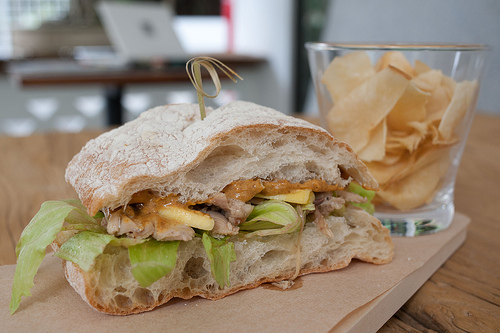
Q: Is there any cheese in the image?
A: Yes, there is cheese.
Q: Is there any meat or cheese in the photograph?
A: Yes, there is cheese.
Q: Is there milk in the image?
A: No, there is no milk.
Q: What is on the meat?
A: The cheese is on the meat.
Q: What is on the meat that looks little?
A: The cheese is on the meat.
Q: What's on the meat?
A: The cheese is on the meat.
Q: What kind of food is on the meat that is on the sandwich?
A: The food is cheese.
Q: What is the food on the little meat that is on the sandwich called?
A: The food is cheese.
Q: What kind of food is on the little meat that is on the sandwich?
A: The food is cheese.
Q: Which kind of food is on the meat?
A: The food is cheese.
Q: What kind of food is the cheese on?
A: The cheese is on the meat.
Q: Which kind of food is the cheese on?
A: The cheese is on the meat.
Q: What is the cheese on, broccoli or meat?
A: The cheese is on meat.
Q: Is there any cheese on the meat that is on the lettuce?
A: Yes, there is cheese on the meat.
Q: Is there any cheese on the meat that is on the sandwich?
A: Yes, there is cheese on the meat.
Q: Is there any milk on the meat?
A: No, there is cheese on the meat.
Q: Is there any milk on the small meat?
A: No, there is cheese on the meat.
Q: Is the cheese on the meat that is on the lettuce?
A: Yes, the cheese is on the meat.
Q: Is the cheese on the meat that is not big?
A: Yes, the cheese is on the meat.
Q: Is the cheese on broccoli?
A: No, the cheese is on the meat.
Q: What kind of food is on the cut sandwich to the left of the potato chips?
A: The food is cheese.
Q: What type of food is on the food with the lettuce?
A: The food is cheese.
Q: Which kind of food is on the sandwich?
A: The food is cheese.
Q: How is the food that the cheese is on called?
A: The food is a sandwich.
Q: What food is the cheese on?
A: The cheese is on the sandwich.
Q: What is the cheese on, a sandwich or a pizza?
A: The cheese is on a sandwich.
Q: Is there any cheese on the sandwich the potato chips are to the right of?
A: Yes, there is cheese on the sandwich.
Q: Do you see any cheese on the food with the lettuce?
A: Yes, there is cheese on the sandwich.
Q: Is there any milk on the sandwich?
A: No, there is cheese on the sandwich.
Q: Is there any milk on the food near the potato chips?
A: No, there is cheese on the sandwich.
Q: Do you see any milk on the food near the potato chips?
A: No, there is cheese on the sandwich.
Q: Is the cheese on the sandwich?
A: Yes, the cheese is on the sandwich.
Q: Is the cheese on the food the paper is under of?
A: Yes, the cheese is on the sandwich.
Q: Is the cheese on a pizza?
A: No, the cheese is on the sandwich.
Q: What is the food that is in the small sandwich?
A: The food is cheese.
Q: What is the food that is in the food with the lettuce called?
A: The food is cheese.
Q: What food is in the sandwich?
A: The food is cheese.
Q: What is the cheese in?
A: The cheese is in the sandwich.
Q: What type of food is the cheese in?
A: The cheese is in the sandwich.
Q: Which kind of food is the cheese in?
A: The cheese is in the sandwich.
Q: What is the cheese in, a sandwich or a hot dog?
A: The cheese is in a sandwich.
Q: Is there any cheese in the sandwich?
A: Yes, there is cheese in the sandwich.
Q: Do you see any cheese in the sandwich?
A: Yes, there is cheese in the sandwich.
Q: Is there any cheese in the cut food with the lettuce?
A: Yes, there is cheese in the sandwich.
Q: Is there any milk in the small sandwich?
A: No, there is cheese in the sandwich.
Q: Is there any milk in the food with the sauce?
A: No, there is cheese in the sandwich.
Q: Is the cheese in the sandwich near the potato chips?
A: Yes, the cheese is in the sandwich.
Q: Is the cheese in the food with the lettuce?
A: Yes, the cheese is in the sandwich.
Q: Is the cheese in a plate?
A: No, the cheese is in the sandwich.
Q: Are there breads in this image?
A: Yes, there is a bread.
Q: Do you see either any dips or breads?
A: Yes, there is a bread.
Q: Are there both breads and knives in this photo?
A: No, there is a bread but no knives.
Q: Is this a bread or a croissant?
A: This is a bread.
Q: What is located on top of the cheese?
A: The bread is on top of the cheese.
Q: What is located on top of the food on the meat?
A: The bread is on top of the cheese.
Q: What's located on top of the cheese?
A: The bread is on top of the cheese.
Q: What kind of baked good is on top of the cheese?
A: The food is a bread.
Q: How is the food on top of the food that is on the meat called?
A: The food is a bread.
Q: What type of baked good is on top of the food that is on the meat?
A: The food is a bread.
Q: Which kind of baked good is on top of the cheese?
A: The food is a bread.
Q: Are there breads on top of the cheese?
A: Yes, there is a bread on top of the cheese.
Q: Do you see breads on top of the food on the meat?
A: Yes, there is a bread on top of the cheese.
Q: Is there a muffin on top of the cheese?
A: No, there is a bread on top of the cheese.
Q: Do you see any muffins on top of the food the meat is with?
A: No, there is a bread on top of the cheese.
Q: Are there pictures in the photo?
A: No, there are no pictures.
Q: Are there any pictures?
A: No, there are no pictures.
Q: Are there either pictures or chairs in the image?
A: No, there are no pictures or chairs.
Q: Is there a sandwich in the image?
A: Yes, there is a sandwich.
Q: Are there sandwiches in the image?
A: Yes, there is a sandwich.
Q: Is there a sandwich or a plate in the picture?
A: Yes, there is a sandwich.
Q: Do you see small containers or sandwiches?
A: Yes, there is a small sandwich.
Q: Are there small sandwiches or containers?
A: Yes, there is a small sandwich.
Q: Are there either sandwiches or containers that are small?
A: Yes, the sandwich is small.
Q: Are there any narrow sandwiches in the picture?
A: Yes, there is a narrow sandwich.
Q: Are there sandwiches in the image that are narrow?
A: Yes, there is a sandwich that is narrow.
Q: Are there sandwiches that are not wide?
A: Yes, there is a narrow sandwich.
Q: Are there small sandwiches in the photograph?
A: Yes, there is a small sandwich.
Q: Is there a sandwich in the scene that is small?
A: Yes, there is a sandwich that is small.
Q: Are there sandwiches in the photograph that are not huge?
A: Yes, there is a small sandwich.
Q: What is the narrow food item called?
A: The food item is a sandwich.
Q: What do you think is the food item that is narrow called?
A: The food item is a sandwich.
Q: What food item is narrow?
A: The food item is a sandwich.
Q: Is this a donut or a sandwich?
A: This is a sandwich.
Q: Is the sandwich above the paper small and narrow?
A: Yes, the sandwich is small and narrow.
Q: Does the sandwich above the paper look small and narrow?
A: Yes, the sandwich is small and narrow.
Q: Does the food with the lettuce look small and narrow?
A: Yes, the sandwich is small and narrow.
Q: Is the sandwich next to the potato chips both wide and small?
A: No, the sandwich is small but narrow.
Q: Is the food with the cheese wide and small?
A: No, the sandwich is small but narrow.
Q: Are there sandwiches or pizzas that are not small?
A: No, there is a sandwich but it is small.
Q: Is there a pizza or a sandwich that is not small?
A: No, there is a sandwich but it is small.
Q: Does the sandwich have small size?
A: Yes, the sandwich is small.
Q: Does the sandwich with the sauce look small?
A: Yes, the sandwich is small.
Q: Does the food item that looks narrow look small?
A: Yes, the sandwich is small.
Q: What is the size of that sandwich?
A: The sandwich is small.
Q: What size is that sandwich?
A: The sandwich is small.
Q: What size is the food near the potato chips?
A: The sandwich is small.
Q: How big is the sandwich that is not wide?
A: The sandwich is small.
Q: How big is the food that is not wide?
A: The sandwich is small.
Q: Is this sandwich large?
A: No, the sandwich is small.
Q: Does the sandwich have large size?
A: No, the sandwich is small.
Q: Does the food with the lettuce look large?
A: No, the sandwich is small.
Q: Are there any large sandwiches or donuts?
A: No, there is a sandwich but it is small.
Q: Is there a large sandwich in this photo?
A: No, there is a sandwich but it is small.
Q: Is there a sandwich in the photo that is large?
A: No, there is a sandwich but it is small.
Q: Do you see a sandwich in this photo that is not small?
A: No, there is a sandwich but it is small.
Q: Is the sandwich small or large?
A: The sandwich is small.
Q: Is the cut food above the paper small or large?
A: The sandwich is small.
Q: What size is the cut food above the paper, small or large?
A: The sandwich is small.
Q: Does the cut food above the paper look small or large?
A: The sandwich is small.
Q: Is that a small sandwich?
A: Yes, that is a small sandwich.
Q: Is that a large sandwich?
A: No, that is a small sandwich.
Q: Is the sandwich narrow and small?
A: Yes, the sandwich is narrow and small.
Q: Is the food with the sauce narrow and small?
A: Yes, the sandwich is narrow and small.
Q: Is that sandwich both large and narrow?
A: No, the sandwich is narrow but small.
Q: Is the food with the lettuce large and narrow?
A: No, the sandwich is narrow but small.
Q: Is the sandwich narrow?
A: Yes, the sandwich is narrow.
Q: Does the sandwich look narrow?
A: Yes, the sandwich is narrow.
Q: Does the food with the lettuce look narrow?
A: Yes, the sandwich is narrow.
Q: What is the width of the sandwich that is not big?
A: The sandwich is narrow.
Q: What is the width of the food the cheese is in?
A: The sandwich is narrow.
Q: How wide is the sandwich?
A: The sandwich is narrow.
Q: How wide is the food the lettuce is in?
A: The sandwich is narrow.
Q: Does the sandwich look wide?
A: No, the sandwich is narrow.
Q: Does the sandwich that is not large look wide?
A: No, the sandwich is narrow.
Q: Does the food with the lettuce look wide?
A: No, the sandwich is narrow.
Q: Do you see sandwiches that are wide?
A: No, there is a sandwich but it is narrow.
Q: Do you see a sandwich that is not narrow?
A: No, there is a sandwich but it is narrow.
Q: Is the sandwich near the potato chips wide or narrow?
A: The sandwich is narrow.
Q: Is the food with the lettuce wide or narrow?
A: The sandwich is narrow.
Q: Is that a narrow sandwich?
A: Yes, that is a narrow sandwich.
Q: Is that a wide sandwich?
A: No, that is a narrow sandwich.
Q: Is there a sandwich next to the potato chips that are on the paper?
A: Yes, there is a sandwich next to the potato chips.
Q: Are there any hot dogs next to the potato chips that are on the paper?
A: No, there is a sandwich next to the potato chips.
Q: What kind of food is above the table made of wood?
A: The food is a sandwich.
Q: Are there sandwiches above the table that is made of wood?
A: Yes, there is a sandwich above the table.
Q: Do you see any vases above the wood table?
A: No, there is a sandwich above the table.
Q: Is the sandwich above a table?
A: Yes, the sandwich is above a table.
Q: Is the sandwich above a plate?
A: No, the sandwich is above a table.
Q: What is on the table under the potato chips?
A: The sandwich is on the table.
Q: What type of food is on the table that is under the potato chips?
A: The food is a sandwich.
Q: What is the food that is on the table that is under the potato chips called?
A: The food is a sandwich.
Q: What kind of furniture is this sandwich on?
A: The sandwich is on the table.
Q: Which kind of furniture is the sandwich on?
A: The sandwich is on the table.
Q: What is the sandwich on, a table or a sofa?
A: The sandwich is on a table.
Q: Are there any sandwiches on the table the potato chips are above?
A: Yes, there is a sandwich on the table.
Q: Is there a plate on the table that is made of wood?
A: No, there is a sandwich on the table.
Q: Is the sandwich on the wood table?
A: Yes, the sandwich is on the table.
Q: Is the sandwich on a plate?
A: No, the sandwich is on the table.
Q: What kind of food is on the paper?
A: The food is a sandwich.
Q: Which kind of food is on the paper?
A: The food is a sandwich.